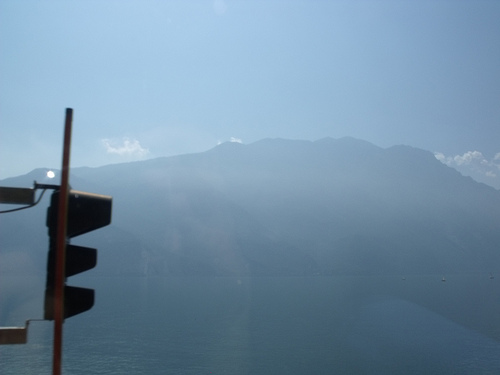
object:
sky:
[1, 2, 496, 213]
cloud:
[434, 143, 499, 180]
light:
[37, 170, 104, 329]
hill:
[210, 140, 247, 157]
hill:
[255, 134, 292, 147]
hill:
[316, 133, 336, 147]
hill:
[337, 136, 356, 148]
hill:
[353, 134, 378, 151]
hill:
[394, 141, 411, 152]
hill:
[413, 143, 434, 161]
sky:
[0, 3, 496, 186]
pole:
[48, 105, 77, 373]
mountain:
[2, 137, 498, 373]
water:
[10, 293, 494, 373]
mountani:
[1, 131, 491, 369]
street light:
[33, 183, 106, 324]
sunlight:
[0, 0, 500, 369]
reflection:
[47, 171, 55, 179]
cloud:
[105, 136, 152, 157]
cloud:
[219, 135, 247, 144]